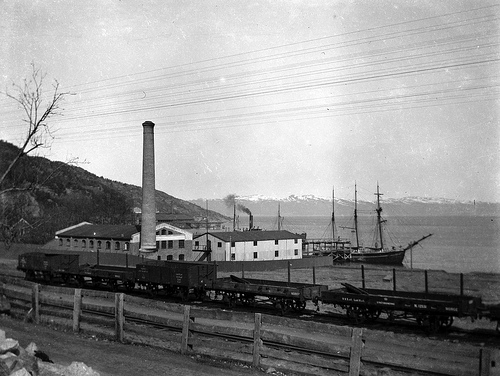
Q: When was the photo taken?
A: Day time.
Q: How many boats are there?
A: One.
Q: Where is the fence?
A: Around the track.